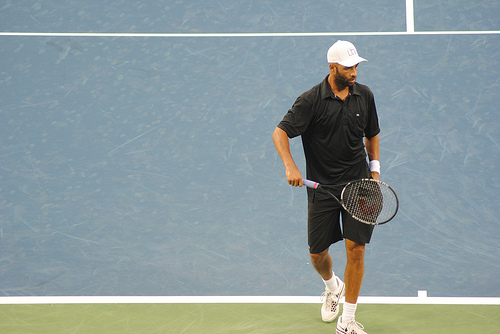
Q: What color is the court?
A: Blue.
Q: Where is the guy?
A: On the court.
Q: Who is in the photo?
A: A guy.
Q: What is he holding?
A: Racket.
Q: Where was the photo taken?
A: Tennis court.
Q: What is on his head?
A: Hat.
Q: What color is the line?
A: White.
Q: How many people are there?
A: One.